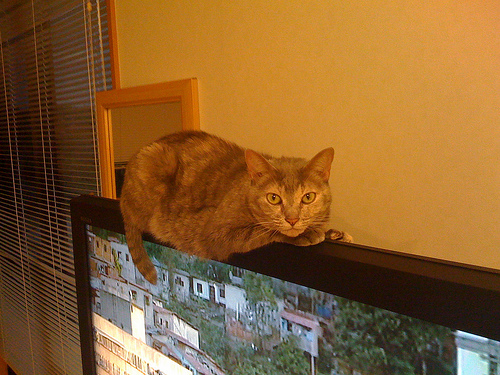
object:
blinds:
[1, 4, 115, 374]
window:
[1, 2, 112, 373]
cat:
[120, 129, 352, 291]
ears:
[237, 146, 336, 177]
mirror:
[96, 78, 201, 210]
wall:
[115, 1, 499, 265]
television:
[53, 194, 498, 373]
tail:
[121, 215, 161, 283]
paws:
[281, 227, 353, 248]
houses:
[88, 242, 327, 372]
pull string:
[78, 1, 106, 117]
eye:
[264, 188, 318, 205]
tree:
[242, 279, 455, 375]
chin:
[284, 230, 303, 238]